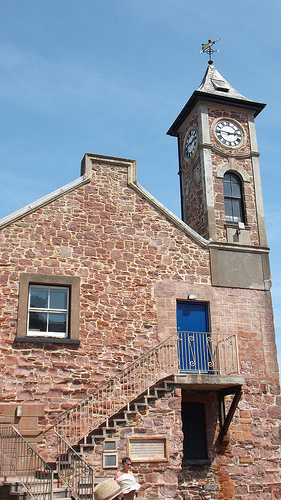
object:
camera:
[234, 220, 248, 239]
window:
[222, 168, 248, 228]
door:
[175, 297, 210, 371]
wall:
[0, 152, 279, 500]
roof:
[164, 38, 267, 138]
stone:
[85, 213, 144, 251]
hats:
[92, 471, 140, 498]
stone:
[73, 355, 89, 367]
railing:
[0, 330, 241, 500]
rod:
[206, 43, 213, 63]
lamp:
[188, 294, 197, 300]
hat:
[92, 476, 131, 499]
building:
[0, 36, 281, 500]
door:
[181, 397, 208, 466]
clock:
[210, 113, 247, 151]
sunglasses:
[125, 461, 133, 467]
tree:
[30, 294, 48, 331]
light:
[184, 292, 204, 300]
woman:
[116, 456, 133, 483]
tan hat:
[92, 473, 124, 498]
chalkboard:
[101, 451, 118, 469]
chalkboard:
[103, 439, 115, 453]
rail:
[76, 314, 245, 415]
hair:
[119, 456, 131, 464]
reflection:
[26, 286, 49, 312]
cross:
[199, 39, 221, 63]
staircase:
[0, 333, 245, 500]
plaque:
[121, 433, 182, 467]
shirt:
[115, 470, 132, 479]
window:
[25, 279, 73, 340]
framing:
[69, 269, 87, 349]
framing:
[114, 439, 120, 468]